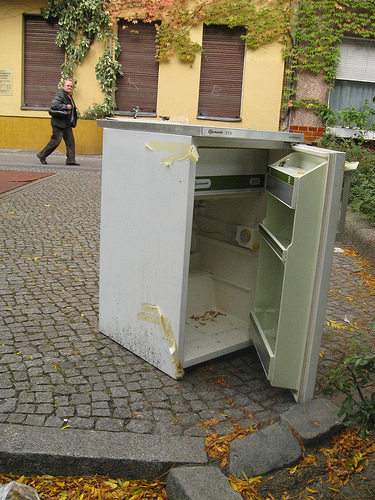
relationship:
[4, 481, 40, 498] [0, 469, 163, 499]
plastic bag on ground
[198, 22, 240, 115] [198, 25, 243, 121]
shades drawn over window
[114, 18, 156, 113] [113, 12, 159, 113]
shades drawn over window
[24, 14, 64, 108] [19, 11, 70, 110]
shades drawn over window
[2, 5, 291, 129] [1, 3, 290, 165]
stucco of building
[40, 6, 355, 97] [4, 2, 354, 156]
plants growing on side of building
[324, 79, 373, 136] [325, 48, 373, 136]
curtain in window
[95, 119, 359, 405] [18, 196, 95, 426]
freezer on sidewalk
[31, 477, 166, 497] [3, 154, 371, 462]
leaves on ground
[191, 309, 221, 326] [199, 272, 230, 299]
bits on shelf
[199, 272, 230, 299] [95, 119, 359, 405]
shelf on freezer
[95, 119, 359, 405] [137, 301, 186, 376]
freezer covered in tape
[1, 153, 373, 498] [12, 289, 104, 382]
ground made of pavers